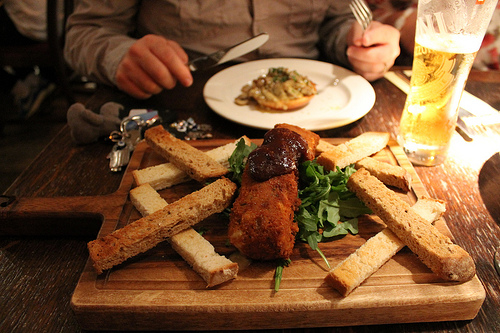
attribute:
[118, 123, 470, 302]
board — wooden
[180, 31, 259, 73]
knife — silver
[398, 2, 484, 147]
glass — tall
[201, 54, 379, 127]
plate — circular, white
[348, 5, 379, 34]
fork — silver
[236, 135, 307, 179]
sauce — red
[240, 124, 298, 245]
meat — breaded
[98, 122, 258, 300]
breadsticks — brown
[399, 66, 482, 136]
napkin — white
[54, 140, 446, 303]
meal — dinner meal, healthy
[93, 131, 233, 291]
sticks — bread sticks